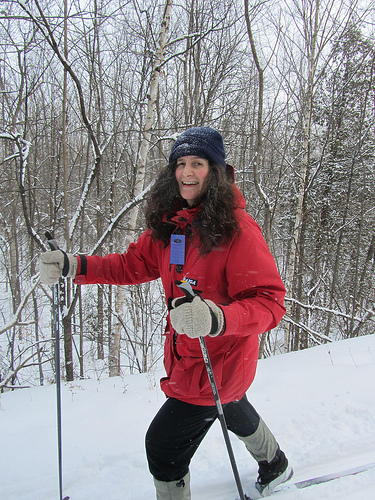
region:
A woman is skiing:
[38, 111, 368, 495]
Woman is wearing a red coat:
[30, 175, 285, 394]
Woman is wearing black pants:
[124, 379, 289, 469]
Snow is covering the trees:
[0, 0, 364, 332]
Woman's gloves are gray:
[26, 235, 236, 350]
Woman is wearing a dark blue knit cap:
[141, 111, 238, 167]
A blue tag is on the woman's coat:
[151, 225, 191, 276]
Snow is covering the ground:
[0, 330, 372, 489]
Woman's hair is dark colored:
[137, 148, 274, 258]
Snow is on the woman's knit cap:
[142, 112, 237, 165]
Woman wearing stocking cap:
[159, 125, 245, 167]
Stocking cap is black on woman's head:
[167, 94, 230, 175]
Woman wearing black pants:
[159, 392, 212, 458]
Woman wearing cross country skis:
[247, 437, 339, 491]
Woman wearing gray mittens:
[155, 272, 228, 366]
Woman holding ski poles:
[156, 267, 226, 432]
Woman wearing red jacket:
[132, 257, 262, 395]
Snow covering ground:
[269, 343, 334, 427]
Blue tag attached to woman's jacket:
[158, 212, 239, 278]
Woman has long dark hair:
[123, 146, 260, 258]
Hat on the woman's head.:
[167, 124, 226, 167]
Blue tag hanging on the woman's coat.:
[168, 233, 187, 264]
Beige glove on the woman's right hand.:
[167, 293, 224, 339]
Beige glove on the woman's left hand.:
[36, 247, 81, 290]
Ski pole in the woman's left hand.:
[46, 241, 64, 496]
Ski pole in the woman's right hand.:
[200, 285, 230, 495]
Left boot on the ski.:
[240, 453, 295, 486]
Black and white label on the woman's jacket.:
[182, 277, 196, 287]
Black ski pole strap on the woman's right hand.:
[204, 299, 221, 339]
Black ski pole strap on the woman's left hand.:
[57, 251, 73, 279]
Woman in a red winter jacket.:
[38, 125, 296, 498]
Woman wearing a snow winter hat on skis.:
[42, 125, 293, 497]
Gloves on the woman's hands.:
[39, 229, 219, 337]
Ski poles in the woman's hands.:
[39, 229, 247, 497]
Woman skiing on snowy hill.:
[35, 123, 373, 498]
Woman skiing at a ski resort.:
[27, 88, 374, 498]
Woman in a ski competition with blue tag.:
[34, 124, 373, 495]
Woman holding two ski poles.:
[37, 126, 286, 498]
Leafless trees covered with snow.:
[2, 10, 370, 389]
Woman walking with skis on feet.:
[17, 80, 364, 498]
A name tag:
[170, 227, 191, 273]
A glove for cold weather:
[164, 288, 241, 336]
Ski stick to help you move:
[33, 243, 87, 493]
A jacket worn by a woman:
[77, 254, 302, 399]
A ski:
[128, 415, 370, 499]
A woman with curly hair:
[127, 121, 285, 344]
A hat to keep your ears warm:
[166, 127, 232, 163]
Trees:
[228, 51, 368, 201]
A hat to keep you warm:
[129, 120, 255, 186]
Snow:
[274, 370, 364, 445]